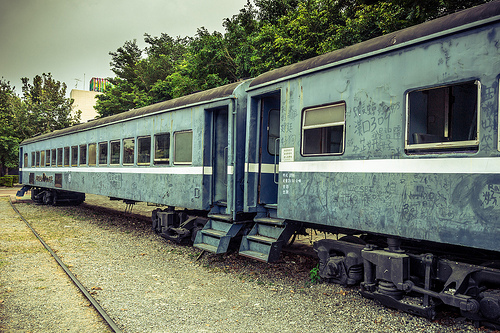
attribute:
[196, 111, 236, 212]
doorway — open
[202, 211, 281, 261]
stairs — blue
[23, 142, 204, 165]
windows — in row, open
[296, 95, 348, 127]
shutters — half closed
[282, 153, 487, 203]
stripe — white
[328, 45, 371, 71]
roof — black, metal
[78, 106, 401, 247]
trains — blue, old, passenger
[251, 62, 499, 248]
train — blue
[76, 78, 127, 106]
building — large, tall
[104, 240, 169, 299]
gravel — abundant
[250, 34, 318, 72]
trees — green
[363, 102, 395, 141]
number — 304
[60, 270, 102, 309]
rail — buried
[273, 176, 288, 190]
letters — stenciled